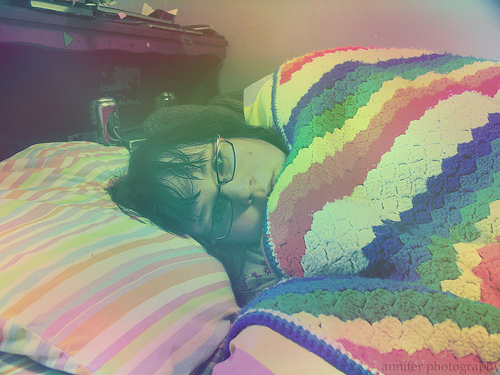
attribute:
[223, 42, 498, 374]
afghan — multi colored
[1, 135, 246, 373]
pillow case — pastel, striped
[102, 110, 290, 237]
hair — black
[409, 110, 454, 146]
ground — colorful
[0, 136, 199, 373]
pillow — multicolor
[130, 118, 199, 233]
hair — black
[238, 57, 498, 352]
sheet — multicolored bed 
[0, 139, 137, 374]
pillowcase — multi colored, striped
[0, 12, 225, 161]
headboard — brown, wood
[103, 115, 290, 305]
girl — thoughtful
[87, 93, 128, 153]
can — empty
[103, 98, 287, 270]
hair — brown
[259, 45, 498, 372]
bedspread — rainbow colored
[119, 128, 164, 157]
clock — alarm clock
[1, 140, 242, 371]
pillow — striped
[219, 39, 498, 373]
blanket — yellow